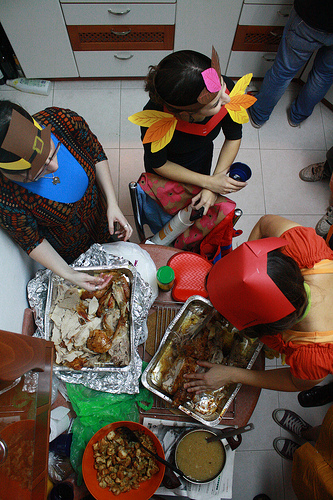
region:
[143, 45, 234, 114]
head of a girl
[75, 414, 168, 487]
bowl on the table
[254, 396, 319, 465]
shoes of the person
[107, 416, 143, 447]
handle of a spoon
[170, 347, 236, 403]
hand of a person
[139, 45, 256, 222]
a person in a costume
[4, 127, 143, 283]
a person in a costume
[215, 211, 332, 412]
a person in a costume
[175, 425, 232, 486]
a bowl of soup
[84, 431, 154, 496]
a plate of food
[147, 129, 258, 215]
a hand of a person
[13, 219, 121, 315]
a hand of a person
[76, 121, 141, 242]
a hand of a person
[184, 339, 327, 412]
a hand of a person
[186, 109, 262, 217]
a hand of a person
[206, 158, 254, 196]
blue plastic cup in right hand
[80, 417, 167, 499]
food in red plastic bowl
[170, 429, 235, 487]
brown gravy in metal cooking pot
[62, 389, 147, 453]
green plastic bag under red bowl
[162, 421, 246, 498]
newspaper under metal pot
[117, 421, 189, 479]
black plastic spoon in red bowl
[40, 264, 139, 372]
carved turkey in metal cooking pan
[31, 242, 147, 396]
metal foil under pan with turkey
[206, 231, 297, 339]
woman wearing red paper hat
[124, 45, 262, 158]
child wearing thanksgiving costume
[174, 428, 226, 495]
brown sauce in the bowl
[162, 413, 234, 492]
brown sauce in the bowl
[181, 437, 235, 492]
brown sauce in the bowl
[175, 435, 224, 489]
brown sauce in the bowl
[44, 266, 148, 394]
meat in the tray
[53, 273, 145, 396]
meat in the tray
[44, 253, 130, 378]
meat in the tray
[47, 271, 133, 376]
meat in the tray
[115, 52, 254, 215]
this is a person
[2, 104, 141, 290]
this is a person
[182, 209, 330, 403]
this is a person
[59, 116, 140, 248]
a hand of a person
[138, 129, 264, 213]
a hand of a person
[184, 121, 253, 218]
a hand of a person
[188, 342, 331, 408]
a hand of a person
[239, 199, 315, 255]
a hand of a person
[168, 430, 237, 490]
a bow of soup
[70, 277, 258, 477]
this is a feast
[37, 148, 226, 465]
this is for thanksgiving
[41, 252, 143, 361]
this is white turkey meat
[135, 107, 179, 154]
yellow and orange leaves on costume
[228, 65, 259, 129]
yellow and orange leaves on costume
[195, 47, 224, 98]
pink leaves on costume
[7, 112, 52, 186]
black brown and yellow hat worn by young boy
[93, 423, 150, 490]
meat in orange bowl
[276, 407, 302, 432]
black and white shoe on child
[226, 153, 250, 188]
blue cup held by girl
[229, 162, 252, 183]
The cup is blue in color.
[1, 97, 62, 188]
The woman is wearing glasses.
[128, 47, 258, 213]
The woman is holding a blue glass.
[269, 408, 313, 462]
The person is wearing white and gray tennis shoes.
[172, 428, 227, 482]
The sauce in the pot is brown in color.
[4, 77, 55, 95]
The cleaning bottle is on the floor.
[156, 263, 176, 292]
The jar on the table is green in color.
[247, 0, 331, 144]
The person standing by the cabinets is wearing blue jeans.